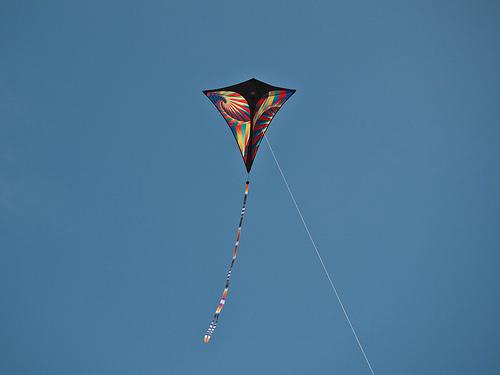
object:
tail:
[201, 172, 249, 344]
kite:
[198, 75, 298, 200]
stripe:
[229, 121, 250, 163]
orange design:
[237, 131, 243, 152]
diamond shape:
[201, 77, 296, 173]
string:
[261, 133, 373, 375]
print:
[205, 91, 251, 127]